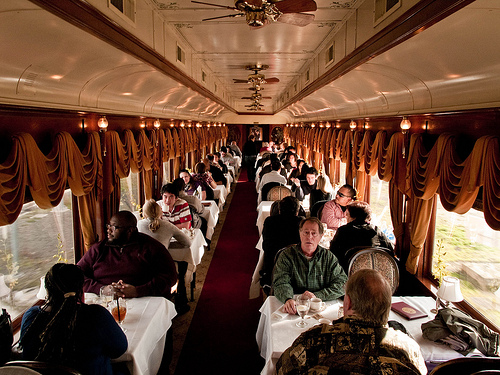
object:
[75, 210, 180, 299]
man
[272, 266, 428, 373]
man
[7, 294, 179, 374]
dinning table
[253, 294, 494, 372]
dinning table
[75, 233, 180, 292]
jacket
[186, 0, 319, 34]
fan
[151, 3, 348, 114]
center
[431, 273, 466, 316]
lamp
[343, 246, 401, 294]
chair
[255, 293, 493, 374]
table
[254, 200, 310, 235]
table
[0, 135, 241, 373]
people sitting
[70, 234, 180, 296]
sweatshirt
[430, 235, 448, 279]
flower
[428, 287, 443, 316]
vase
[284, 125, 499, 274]
curtains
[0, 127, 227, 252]
curtains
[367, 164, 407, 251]
windows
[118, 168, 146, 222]
windows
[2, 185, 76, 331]
window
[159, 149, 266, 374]
aisle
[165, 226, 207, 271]
tables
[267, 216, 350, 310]
man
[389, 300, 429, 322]
book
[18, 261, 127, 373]
woman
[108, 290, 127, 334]
glass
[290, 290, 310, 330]
glass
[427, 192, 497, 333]
window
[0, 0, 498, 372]
train